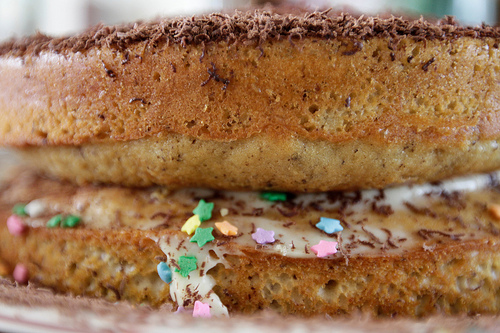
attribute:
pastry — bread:
[0, 4, 492, 314]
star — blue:
[314, 212, 349, 239]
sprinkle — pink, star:
[249, 219, 280, 251]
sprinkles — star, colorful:
[168, 192, 233, 255]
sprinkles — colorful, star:
[252, 210, 391, 256]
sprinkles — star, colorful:
[18, 199, 74, 231]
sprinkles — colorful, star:
[178, 183, 251, 258]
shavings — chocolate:
[101, 38, 166, 57]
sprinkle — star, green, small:
[180, 189, 220, 229]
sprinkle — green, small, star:
[187, 218, 227, 251]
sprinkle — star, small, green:
[174, 250, 199, 280]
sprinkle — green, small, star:
[55, 214, 81, 240]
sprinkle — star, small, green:
[53, 204, 101, 234]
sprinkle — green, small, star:
[266, 181, 302, 216]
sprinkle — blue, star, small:
[308, 193, 344, 244]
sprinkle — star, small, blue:
[148, 253, 170, 284]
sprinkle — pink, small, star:
[308, 235, 342, 259]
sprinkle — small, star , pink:
[190, 295, 208, 315]